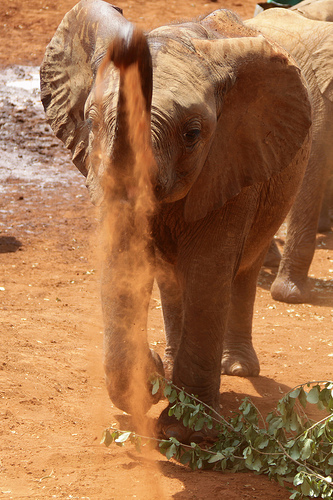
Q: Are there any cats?
A: No, there are no cats.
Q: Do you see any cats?
A: No, there are no cats.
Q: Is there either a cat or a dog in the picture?
A: No, there are no cats or dogs.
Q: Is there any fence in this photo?
A: No, there are no fences.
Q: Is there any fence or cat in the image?
A: No, there are no fences or cats.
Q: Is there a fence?
A: No, there are no fences.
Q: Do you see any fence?
A: No, there are no fences.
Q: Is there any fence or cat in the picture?
A: No, there are no fences or cats.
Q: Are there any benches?
A: No, there are no benches.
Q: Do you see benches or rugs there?
A: No, there are no benches or rugs.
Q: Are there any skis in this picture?
A: No, there are no skis.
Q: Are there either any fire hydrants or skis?
A: No, there are no skis or fire hydrants.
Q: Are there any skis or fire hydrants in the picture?
A: No, there are no skis or fire hydrants.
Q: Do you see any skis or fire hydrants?
A: No, there are no skis or fire hydrants.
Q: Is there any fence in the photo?
A: No, there are no fences.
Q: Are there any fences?
A: No, there are no fences.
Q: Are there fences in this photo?
A: No, there are no fences.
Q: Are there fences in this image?
A: No, there are no fences.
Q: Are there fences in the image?
A: No, there are no fences.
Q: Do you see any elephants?
A: Yes, there is an elephant.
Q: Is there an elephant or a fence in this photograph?
A: Yes, there is an elephant.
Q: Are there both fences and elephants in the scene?
A: No, there is an elephant but no fences.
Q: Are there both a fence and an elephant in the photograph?
A: No, there is an elephant but no fences.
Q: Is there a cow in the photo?
A: No, there are no cows.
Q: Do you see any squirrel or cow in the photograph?
A: No, there are no cows or squirrels.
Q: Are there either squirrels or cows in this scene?
A: No, there are no cows or squirrels.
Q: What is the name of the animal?
A: The animal is an elephant.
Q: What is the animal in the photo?
A: The animal is an elephant.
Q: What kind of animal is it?
A: The animal is an elephant.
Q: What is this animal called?
A: That is an elephant.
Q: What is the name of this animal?
A: That is an elephant.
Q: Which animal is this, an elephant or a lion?
A: That is an elephant.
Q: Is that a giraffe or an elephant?
A: That is an elephant.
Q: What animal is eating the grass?
A: The elephant is eating the grass.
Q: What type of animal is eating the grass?
A: The animal is an elephant.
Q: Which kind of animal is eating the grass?
A: The animal is an elephant.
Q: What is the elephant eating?
A: The elephant is eating grass.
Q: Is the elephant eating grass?
A: Yes, the elephant is eating grass.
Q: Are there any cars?
A: No, there are no cars.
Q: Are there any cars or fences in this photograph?
A: No, there are no cars or fences.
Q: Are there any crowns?
A: No, there are no crowns.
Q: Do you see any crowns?
A: No, there are no crowns.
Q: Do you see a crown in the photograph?
A: No, there are no crowns.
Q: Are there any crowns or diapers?
A: No, there are no crowns or diapers.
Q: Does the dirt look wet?
A: Yes, the dirt is wet.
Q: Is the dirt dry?
A: No, the dirt is wet.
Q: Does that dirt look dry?
A: No, the dirt is wet.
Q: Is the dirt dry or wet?
A: The dirt is wet.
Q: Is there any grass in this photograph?
A: Yes, there is grass.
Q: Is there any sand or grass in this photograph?
A: Yes, there is grass.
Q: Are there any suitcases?
A: No, there are no suitcases.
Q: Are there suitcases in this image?
A: No, there are no suitcases.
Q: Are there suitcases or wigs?
A: No, there are no suitcases or wigs.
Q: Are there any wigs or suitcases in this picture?
A: No, there are no suitcases or wigs.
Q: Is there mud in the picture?
A: Yes, there is mud.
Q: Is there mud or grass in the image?
A: Yes, there is mud.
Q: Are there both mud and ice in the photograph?
A: No, there is mud but no ice.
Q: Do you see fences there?
A: No, there are no fences.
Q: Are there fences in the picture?
A: No, there are no fences.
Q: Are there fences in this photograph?
A: No, there are no fences.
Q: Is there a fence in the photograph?
A: No, there are no fences.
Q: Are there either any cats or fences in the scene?
A: No, there are no fences or cats.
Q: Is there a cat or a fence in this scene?
A: No, there are no fences or cats.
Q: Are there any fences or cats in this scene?
A: No, there are no fences or cats.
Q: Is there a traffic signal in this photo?
A: No, there are no traffic lights.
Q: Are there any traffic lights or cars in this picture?
A: No, there are no traffic lights or cars.